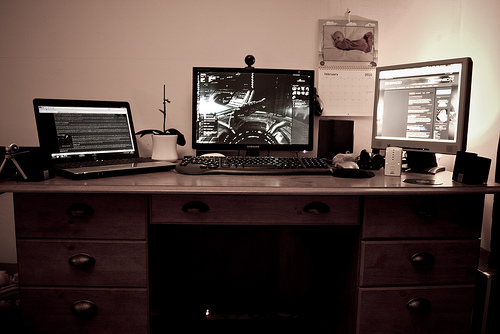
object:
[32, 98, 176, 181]
laptop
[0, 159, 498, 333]
desk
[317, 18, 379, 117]
calendar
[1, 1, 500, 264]
wall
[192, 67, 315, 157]
monitor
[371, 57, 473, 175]
monitor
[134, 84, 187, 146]
plant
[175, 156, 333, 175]
keyboard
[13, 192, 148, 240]
drawer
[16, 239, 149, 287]
drawer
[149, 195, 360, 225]
drawer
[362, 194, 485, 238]
drawer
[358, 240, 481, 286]
drawer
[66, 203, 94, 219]
handle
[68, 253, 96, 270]
handle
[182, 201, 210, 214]
handle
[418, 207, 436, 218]
handle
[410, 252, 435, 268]
handle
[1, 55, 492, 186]
objects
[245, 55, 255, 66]
webcam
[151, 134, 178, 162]
pot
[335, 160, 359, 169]
computer mouse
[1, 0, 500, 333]
office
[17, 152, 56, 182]
speaker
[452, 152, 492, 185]
speaker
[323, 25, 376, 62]
picture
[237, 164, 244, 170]
buttons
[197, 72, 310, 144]
image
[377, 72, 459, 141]
image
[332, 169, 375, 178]
pad